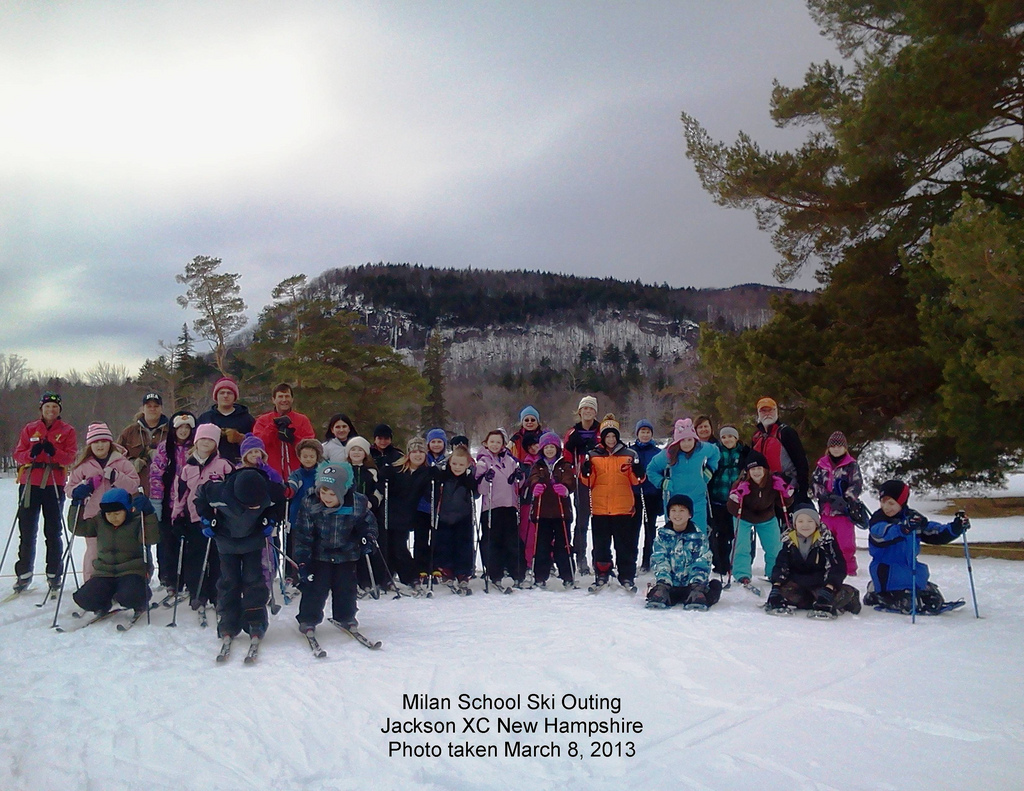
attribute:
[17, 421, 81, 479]
jacket — red 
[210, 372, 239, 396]
hat — red 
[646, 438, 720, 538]
snow suit — turqouise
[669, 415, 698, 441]
hat — pink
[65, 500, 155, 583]
jacket — olive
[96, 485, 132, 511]
hat — blue, black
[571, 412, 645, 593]
person — orange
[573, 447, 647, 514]
coat — black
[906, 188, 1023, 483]
tree — tall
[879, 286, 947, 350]
leaves — green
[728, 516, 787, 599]
snowpants — turquoise 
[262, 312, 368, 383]
leaves — green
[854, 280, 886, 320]
leaves — green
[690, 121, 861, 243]
leaves — green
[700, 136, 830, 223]
leaves — green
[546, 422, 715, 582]
parka — orange, bright 